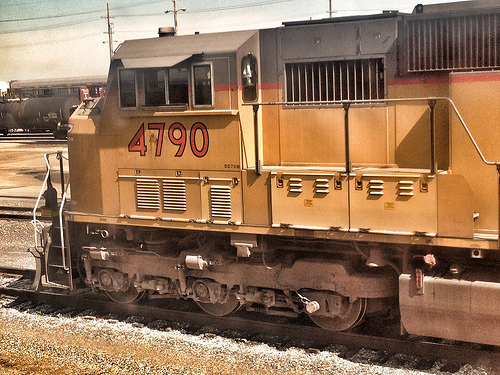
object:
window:
[280, 55, 386, 107]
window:
[396, 11, 500, 73]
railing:
[403, 11, 499, 72]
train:
[24, 1, 500, 351]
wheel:
[191, 275, 242, 318]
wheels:
[83, 242, 385, 332]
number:
[128, 121, 210, 157]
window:
[192, 62, 215, 109]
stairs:
[25, 149, 74, 292]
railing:
[284, 55, 389, 107]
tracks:
[0, 266, 499, 375]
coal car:
[0, 75, 108, 139]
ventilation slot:
[315, 178, 329, 194]